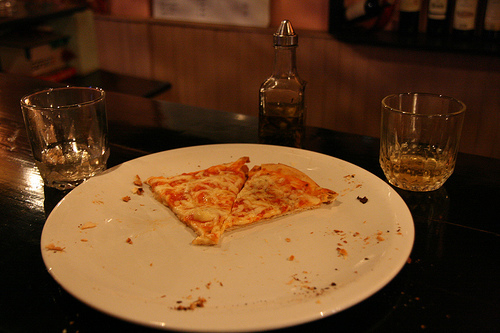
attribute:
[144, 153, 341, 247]
pizza — slices, white, red, plain, small, yellow, orange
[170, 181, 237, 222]
cheese — white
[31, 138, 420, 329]
plate — white, round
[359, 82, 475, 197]
glass — empty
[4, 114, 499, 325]
table top — brown, wood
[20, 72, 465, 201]
glasses — identical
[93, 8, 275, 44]
slat — wooden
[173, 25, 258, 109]
paneling — wood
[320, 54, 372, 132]
wall — brown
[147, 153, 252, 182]
crust — thin